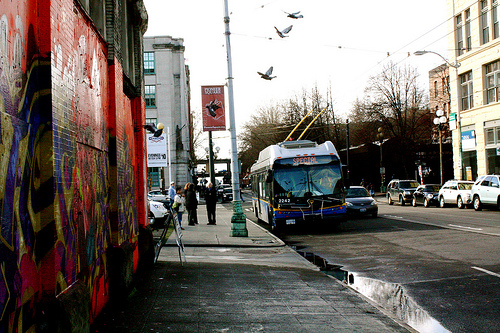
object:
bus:
[240, 135, 350, 234]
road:
[217, 188, 497, 331]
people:
[183, 182, 204, 227]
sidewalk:
[139, 202, 411, 332]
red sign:
[201, 84, 225, 134]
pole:
[220, 1, 248, 239]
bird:
[257, 65, 281, 81]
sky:
[124, 0, 445, 175]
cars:
[386, 178, 421, 207]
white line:
[466, 263, 500, 278]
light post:
[413, 48, 462, 192]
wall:
[0, 0, 148, 332]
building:
[426, 64, 457, 143]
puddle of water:
[283, 238, 451, 332]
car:
[342, 186, 378, 220]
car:
[435, 178, 475, 210]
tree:
[347, 59, 438, 177]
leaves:
[262, 126, 282, 139]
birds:
[270, 24, 296, 40]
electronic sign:
[284, 157, 328, 168]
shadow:
[324, 216, 444, 235]